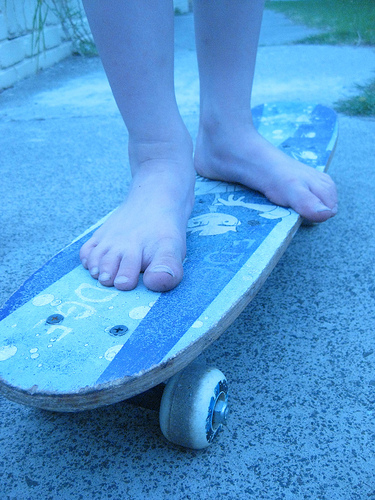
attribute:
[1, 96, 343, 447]
skateboard — blue, nice, clean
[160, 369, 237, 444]
wheels — white, small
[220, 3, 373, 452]
ground — speckled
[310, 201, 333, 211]
toenail — trimmed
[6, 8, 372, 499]
picture — blue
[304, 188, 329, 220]
toe — clean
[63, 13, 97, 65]
weed — grown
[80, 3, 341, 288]
person — standing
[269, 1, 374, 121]
grass — green